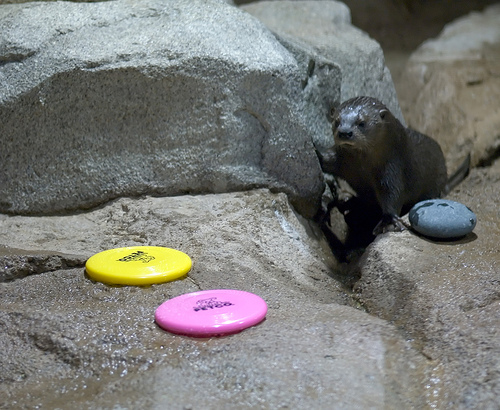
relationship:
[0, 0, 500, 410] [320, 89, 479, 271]
rock near animal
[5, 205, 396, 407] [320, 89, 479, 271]
rock near animal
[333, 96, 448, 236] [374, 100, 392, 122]
animal has ear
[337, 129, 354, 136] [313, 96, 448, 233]
nose on seal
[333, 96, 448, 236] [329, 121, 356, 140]
animal has nose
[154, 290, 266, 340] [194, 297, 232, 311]
frisbee has graphic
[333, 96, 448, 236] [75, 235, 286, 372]
animal looks at frisbees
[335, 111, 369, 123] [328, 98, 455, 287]
eyes of otter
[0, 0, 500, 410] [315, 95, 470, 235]
rock around otter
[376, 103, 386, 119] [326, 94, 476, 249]
ear of otter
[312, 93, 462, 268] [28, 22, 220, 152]
animal between rocks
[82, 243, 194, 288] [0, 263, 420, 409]
frisbee on rock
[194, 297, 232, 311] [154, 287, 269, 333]
graphic on frisbee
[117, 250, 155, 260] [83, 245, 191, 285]
graphics on frisbee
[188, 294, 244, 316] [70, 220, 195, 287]
graphic on frisbee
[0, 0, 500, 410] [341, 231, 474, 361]
rock on rock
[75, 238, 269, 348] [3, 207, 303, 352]
frisbees on rock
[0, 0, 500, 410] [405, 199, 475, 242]
rock with stone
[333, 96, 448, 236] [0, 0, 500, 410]
animal between rock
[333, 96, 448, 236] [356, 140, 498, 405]
animal between rock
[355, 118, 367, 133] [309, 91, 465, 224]
eye of seal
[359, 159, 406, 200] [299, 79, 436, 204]
fur on seal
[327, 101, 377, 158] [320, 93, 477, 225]
head of seal